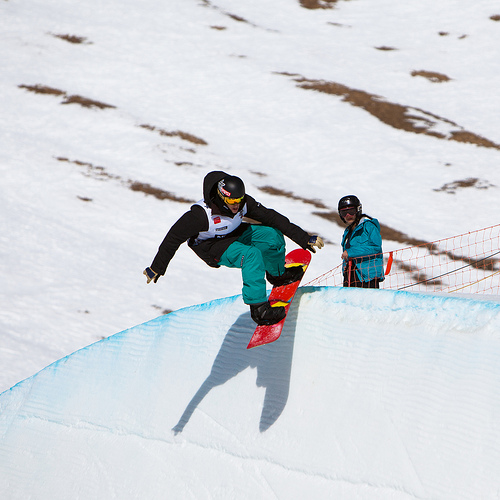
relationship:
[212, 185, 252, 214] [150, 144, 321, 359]
face of person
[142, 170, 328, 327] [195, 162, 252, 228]
man wearing helmet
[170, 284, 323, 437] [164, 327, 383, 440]
shadow on ice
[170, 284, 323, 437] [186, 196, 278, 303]
shadow of person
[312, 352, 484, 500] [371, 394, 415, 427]
sun shine on ice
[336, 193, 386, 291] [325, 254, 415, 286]
guy walking in ice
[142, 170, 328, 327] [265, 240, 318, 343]
man jumping in ice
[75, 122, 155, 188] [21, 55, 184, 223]
mark in ice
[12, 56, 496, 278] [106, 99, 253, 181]
snow on ground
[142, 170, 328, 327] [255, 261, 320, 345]
man has snowboard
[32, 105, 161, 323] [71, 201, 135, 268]
track in snow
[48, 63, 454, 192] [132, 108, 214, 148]
dirt in snow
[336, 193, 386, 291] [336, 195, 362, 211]
guy wearing helmet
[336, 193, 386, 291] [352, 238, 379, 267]
guy has jacket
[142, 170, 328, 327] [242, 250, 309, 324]
man has ski boots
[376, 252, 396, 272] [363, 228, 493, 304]
flag on fence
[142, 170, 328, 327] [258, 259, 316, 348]
man on snowboard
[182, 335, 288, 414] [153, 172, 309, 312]
shadow under man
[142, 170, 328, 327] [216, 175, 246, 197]
man wearing helmet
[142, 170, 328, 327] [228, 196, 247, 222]
man wearing goggles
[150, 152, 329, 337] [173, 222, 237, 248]
man wearing jacket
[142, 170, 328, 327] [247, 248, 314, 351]
man standing on snowboard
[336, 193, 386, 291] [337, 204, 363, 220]
guy wearing goggles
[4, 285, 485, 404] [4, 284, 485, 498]
line in snow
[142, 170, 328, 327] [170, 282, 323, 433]
man has shadow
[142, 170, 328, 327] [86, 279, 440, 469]
man on ground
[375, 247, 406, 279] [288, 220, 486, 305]
ribbon on net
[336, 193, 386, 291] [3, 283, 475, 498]
guy standing behind hill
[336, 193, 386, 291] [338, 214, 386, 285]
guy in coat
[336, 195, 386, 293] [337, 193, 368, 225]
guy in helmet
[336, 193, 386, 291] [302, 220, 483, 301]
guy behind net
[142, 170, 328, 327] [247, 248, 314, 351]
man on snowboard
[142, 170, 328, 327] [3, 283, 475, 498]
man on hill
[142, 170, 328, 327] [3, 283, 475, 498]
man riding on hill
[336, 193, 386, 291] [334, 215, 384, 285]
guy in jacket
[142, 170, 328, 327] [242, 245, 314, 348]
man riding snowboard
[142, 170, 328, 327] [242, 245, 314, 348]
man on snowboard